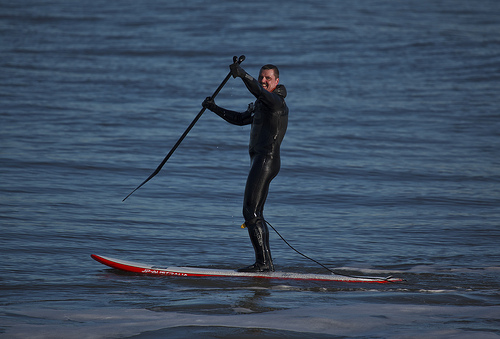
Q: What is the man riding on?
A: A surfboard.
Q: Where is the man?
A: On the water.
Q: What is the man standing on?
A: A surfboard.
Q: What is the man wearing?
A: A black wet suit.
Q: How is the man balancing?
A: With his legs braced apart.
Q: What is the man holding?
A: An oar.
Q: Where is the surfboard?
A: Underneath the man.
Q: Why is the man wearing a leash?
A: So he doesn't lose his board.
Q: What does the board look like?
A: Red, white and long.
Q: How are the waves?
A: Calm and small.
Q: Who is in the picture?
A: A man.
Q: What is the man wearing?
A: A wetsuit.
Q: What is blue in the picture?
A: The water.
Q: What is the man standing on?
A: A surfboard.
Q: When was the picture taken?
A: Afternoon.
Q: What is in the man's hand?
A: A pole.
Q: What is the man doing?
A: Surfing.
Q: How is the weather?
A: Sunny.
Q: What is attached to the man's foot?
A: Cord.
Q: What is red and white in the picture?
A: A surfboard.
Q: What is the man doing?
A: Paddle boarding.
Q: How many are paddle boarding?
A: One.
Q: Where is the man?
A: Ocean.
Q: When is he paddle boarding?
A: Daytime.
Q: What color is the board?
A: Red and white.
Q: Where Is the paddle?
A: On the right side of board.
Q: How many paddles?
A: One.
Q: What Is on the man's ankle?
A: String.